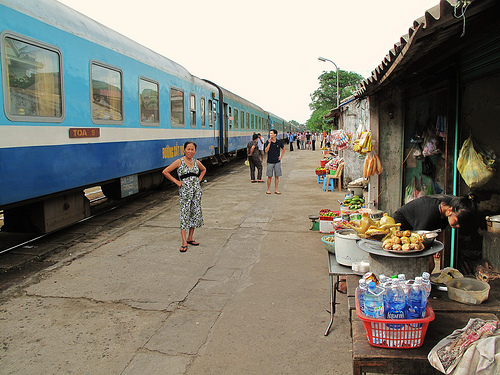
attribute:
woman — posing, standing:
[160, 142, 207, 251]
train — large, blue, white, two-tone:
[3, 1, 306, 246]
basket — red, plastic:
[353, 281, 435, 349]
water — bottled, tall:
[360, 272, 431, 345]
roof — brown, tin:
[350, 0, 485, 94]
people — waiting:
[246, 128, 334, 195]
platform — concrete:
[3, 132, 335, 372]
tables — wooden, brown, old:
[343, 273, 498, 373]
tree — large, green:
[305, 70, 364, 130]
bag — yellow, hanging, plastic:
[455, 133, 499, 188]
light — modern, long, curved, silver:
[315, 54, 340, 111]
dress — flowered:
[178, 157, 204, 230]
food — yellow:
[353, 213, 426, 253]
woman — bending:
[395, 188, 480, 230]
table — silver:
[324, 235, 357, 336]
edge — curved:
[324, 250, 356, 276]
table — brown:
[351, 309, 500, 375]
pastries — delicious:
[382, 229, 428, 254]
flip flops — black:
[178, 238, 201, 254]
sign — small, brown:
[68, 126, 100, 139]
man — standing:
[264, 128, 285, 196]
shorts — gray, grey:
[265, 161, 283, 179]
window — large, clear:
[1, 32, 66, 122]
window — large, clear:
[88, 58, 126, 126]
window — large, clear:
[138, 73, 161, 128]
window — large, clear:
[169, 85, 186, 127]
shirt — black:
[262, 140, 284, 162]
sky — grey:
[55, 2, 440, 127]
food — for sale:
[308, 128, 428, 254]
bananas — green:
[343, 193, 366, 212]